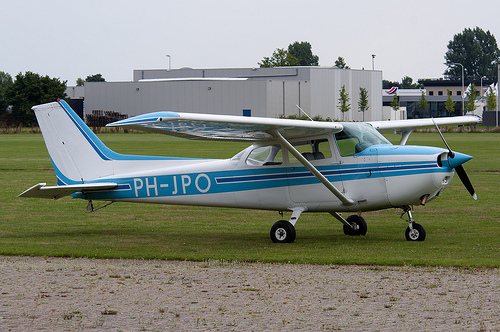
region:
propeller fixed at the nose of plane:
[17, 91, 482, 249]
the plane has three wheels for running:
[19, 99, 482, 246]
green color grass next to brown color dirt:
[4, 140, 496, 327]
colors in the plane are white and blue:
[19, 95, 480, 249]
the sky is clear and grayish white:
[0, 0, 485, 66]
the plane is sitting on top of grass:
[19, 96, 480, 249]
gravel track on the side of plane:
[115, 277, 280, 304]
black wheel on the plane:
[266, 215, 303, 245]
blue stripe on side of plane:
[205, 168, 342, 186]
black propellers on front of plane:
[428, 123, 492, 208]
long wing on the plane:
[129, 83, 488, 148]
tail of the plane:
[19, 87, 113, 171]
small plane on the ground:
[30, 78, 498, 252]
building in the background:
[89, 50, 383, 118]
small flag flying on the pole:
[383, 72, 412, 99]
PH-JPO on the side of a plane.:
[131, 172, 210, 197]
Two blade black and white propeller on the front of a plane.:
[430, 117, 479, 202]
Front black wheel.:
[405, 220, 427, 242]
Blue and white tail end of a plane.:
[30, 98, 135, 184]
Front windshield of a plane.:
[327, 118, 389, 158]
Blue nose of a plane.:
[447, 145, 471, 168]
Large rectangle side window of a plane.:
[281, 135, 333, 165]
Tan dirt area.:
[2, 254, 498, 330]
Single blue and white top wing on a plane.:
[105, 111, 482, 138]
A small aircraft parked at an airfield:
[1, 1, 498, 268]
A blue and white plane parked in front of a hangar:
[3, 0, 498, 266]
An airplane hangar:
[64, 66, 385, 131]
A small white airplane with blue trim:
[17, 97, 479, 247]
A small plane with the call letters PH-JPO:
[18, 98, 478, 243]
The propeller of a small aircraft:
[430, 115, 477, 200]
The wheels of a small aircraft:
[270, 209, 424, 244]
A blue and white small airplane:
[18, 98, 480, 240]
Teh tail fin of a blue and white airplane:
[30, 99, 108, 198]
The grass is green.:
[19, 196, 276, 264]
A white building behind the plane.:
[84, 68, 399, 126]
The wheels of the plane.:
[266, 218, 391, 241]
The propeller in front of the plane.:
[440, 113, 484, 197]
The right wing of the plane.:
[27, 167, 124, 202]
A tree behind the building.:
[438, 24, 495, 81]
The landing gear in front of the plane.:
[403, 207, 434, 242]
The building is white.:
[74, 58, 385, 137]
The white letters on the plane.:
[128, 170, 213, 198]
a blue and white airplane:
[12, 78, 494, 260]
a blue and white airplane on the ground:
[13, 80, 490, 278]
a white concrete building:
[78, 71, 395, 141]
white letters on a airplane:
[131, 167, 213, 197]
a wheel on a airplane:
[265, 211, 294, 242]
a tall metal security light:
[445, 60, 467, 120]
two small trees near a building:
[332, 81, 373, 116]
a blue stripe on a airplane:
[204, 158, 446, 191]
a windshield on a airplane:
[335, 117, 394, 159]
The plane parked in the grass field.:
[18, 95, 487, 245]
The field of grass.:
[2, 127, 498, 263]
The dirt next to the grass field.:
[0, 255, 499, 330]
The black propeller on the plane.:
[431, 117, 480, 202]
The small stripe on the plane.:
[214, 162, 438, 183]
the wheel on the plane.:
[264, 218, 297, 244]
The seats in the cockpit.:
[301, 147, 327, 163]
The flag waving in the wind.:
[386, 83, 397, 95]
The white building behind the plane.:
[84, 64, 408, 121]